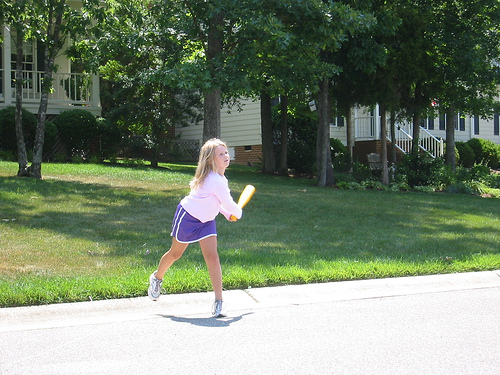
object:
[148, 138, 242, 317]
girl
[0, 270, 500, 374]
street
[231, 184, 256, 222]
bat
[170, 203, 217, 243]
shorts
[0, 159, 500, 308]
lawn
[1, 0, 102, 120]
houses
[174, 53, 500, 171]
houses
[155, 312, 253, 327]
shadow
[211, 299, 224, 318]
sneakers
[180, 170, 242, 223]
jacket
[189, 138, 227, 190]
hair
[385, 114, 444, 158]
steps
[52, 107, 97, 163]
shrubs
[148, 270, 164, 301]
foot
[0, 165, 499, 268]
shadow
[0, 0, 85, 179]
tree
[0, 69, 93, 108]
railing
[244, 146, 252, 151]
window